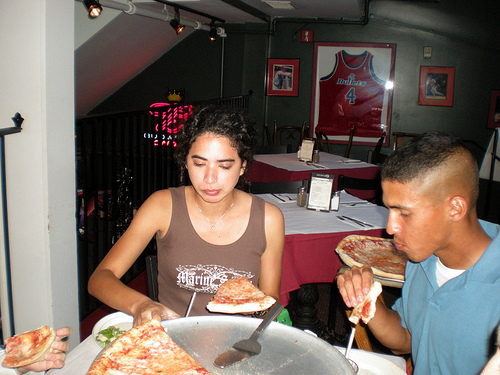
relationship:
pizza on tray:
[108, 325, 217, 374] [185, 311, 319, 374]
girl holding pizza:
[146, 113, 291, 312] [108, 325, 217, 374]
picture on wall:
[418, 61, 456, 117] [267, 28, 495, 156]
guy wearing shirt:
[376, 148, 459, 281] [400, 245, 490, 341]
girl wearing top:
[146, 113, 291, 312] [153, 192, 266, 303]